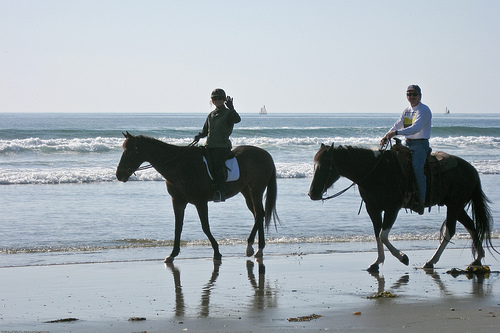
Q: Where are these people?
A: Beach.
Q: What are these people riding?
A: Horses.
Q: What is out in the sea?
A: A boat.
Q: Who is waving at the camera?
A: A woman.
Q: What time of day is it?
A: Afternoon.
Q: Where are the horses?
A: The sea.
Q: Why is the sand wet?
A: Water.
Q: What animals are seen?
A: Horses.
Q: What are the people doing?
A: Riding horses.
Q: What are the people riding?
A: Horses.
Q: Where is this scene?
A: Beach.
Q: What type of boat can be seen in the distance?
A: Sail boat.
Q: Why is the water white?
A: Waves breaking.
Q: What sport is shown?
A: Horseback riding.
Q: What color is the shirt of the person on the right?
A: White.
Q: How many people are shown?
A: Two.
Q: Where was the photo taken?
A: Beach.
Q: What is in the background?
A: Ocean.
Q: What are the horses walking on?
A: Sand.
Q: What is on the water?
A: Ship.